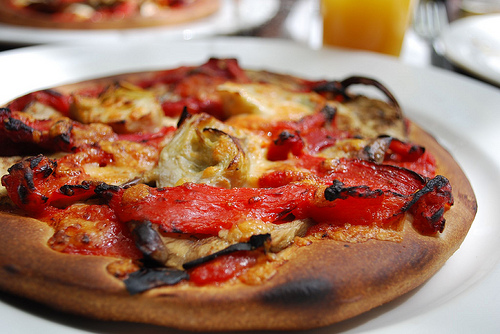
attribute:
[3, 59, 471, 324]
pizza — round, burnt, red, small, yellow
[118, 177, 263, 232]
pepperoni — re, burnt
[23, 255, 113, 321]
crust — golden, burnt, brown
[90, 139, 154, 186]
cheese — melted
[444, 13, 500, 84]
plate — white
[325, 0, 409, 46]
juice — orange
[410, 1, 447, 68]
fork — metal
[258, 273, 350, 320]
crust — burnt, black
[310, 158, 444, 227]
pepper — red, charred